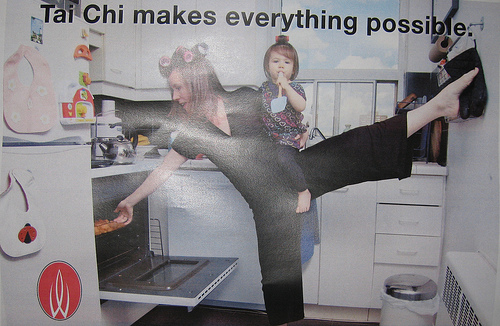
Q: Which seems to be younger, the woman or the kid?
A: The kid is younger than the woman.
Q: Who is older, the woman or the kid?
A: The woman is older than the kid.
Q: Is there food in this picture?
A: Yes, there is food.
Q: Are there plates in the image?
A: No, there are no plates.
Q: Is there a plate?
A: No, there are no plates.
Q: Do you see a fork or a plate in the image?
A: No, there are no plates or forks.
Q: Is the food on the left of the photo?
A: Yes, the food is on the left of the image.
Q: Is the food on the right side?
A: No, the food is on the left of the image.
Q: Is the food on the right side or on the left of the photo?
A: The food is on the left of the image.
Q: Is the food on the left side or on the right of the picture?
A: The food is on the left of the image.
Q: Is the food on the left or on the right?
A: The food is on the left of the image.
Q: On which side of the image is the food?
A: The food is on the left of the image.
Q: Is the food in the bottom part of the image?
A: Yes, the food is in the bottom of the image.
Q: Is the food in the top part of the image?
A: No, the food is in the bottom of the image.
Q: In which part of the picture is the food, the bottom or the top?
A: The food is in the bottom of the image.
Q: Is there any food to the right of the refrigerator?
A: Yes, there is food to the right of the refrigerator.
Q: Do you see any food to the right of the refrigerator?
A: Yes, there is food to the right of the refrigerator.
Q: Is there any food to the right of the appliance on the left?
A: Yes, there is food to the right of the refrigerator.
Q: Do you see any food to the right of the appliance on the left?
A: Yes, there is food to the right of the refrigerator.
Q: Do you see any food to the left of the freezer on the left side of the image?
A: No, the food is to the right of the freezer.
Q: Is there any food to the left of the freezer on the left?
A: No, the food is to the right of the freezer.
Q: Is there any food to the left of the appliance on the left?
A: No, the food is to the right of the freezer.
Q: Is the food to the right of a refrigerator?
A: Yes, the food is to the right of a refrigerator.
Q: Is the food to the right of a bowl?
A: No, the food is to the right of a refrigerator.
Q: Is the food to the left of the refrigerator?
A: No, the food is to the right of the refrigerator.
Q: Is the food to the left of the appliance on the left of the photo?
A: No, the food is to the right of the refrigerator.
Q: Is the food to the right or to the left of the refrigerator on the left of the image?
A: The food is to the right of the freezer.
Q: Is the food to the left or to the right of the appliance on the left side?
A: The food is to the right of the freezer.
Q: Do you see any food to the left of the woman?
A: Yes, there is food to the left of the woman.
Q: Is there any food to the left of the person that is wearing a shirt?
A: Yes, there is food to the left of the woman.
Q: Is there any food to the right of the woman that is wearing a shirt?
A: No, the food is to the left of the woman.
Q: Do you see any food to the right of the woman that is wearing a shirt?
A: No, the food is to the left of the woman.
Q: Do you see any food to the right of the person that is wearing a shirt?
A: No, the food is to the left of the woman.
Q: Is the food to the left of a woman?
A: Yes, the food is to the left of a woman.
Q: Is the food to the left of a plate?
A: No, the food is to the left of a woman.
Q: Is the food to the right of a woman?
A: No, the food is to the left of a woman.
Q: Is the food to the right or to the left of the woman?
A: The food is to the left of the woman.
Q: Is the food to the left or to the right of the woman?
A: The food is to the left of the woman.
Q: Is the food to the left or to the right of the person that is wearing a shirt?
A: The food is to the left of the woman.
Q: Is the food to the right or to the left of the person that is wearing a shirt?
A: The food is to the left of the woman.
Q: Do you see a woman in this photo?
A: Yes, there is a woman.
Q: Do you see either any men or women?
A: Yes, there is a woman.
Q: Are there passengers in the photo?
A: No, there are no passengers.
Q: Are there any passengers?
A: No, there are no passengers.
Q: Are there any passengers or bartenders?
A: No, there are no passengers or bartenders.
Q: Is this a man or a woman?
A: This is a woman.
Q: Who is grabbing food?
A: The woman is grabbing food.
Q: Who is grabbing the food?
A: The woman is grabbing food.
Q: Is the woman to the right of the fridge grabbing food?
A: Yes, the woman is grabbing food.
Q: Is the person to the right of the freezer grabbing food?
A: Yes, the woman is grabbing food.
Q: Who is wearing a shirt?
A: The woman is wearing a shirt.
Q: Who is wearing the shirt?
A: The woman is wearing a shirt.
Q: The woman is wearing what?
A: The woman is wearing a shirt.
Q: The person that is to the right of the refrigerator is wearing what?
A: The woman is wearing a shirt.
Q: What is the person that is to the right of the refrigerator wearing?
A: The woman is wearing a shirt.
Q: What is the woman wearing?
A: The woman is wearing a shirt.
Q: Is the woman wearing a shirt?
A: Yes, the woman is wearing a shirt.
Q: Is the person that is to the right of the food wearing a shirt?
A: Yes, the woman is wearing a shirt.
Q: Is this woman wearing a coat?
A: No, the woman is wearing a shirt.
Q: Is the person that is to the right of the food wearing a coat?
A: No, the woman is wearing a shirt.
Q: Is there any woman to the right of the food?
A: Yes, there is a woman to the right of the food.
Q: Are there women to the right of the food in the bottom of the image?
A: Yes, there is a woman to the right of the food.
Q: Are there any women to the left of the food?
A: No, the woman is to the right of the food.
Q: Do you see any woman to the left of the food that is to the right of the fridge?
A: No, the woman is to the right of the food.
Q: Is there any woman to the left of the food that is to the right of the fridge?
A: No, the woman is to the right of the food.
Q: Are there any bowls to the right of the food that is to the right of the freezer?
A: No, there is a woman to the right of the food.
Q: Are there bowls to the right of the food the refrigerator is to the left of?
A: No, there is a woman to the right of the food.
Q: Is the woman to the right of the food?
A: Yes, the woman is to the right of the food.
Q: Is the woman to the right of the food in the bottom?
A: Yes, the woman is to the right of the food.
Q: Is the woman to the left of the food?
A: No, the woman is to the right of the food.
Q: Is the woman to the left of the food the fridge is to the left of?
A: No, the woman is to the right of the food.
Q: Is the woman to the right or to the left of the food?
A: The woman is to the right of the food.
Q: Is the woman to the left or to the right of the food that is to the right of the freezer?
A: The woman is to the right of the food.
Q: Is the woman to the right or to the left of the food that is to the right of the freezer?
A: The woman is to the right of the food.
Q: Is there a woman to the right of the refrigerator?
A: Yes, there is a woman to the right of the refrigerator.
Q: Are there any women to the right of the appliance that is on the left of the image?
A: Yes, there is a woman to the right of the refrigerator.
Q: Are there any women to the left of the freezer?
A: No, the woman is to the right of the freezer.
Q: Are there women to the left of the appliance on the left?
A: No, the woman is to the right of the freezer.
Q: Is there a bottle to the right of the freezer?
A: No, there is a woman to the right of the freezer.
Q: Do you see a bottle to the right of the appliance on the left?
A: No, there is a woman to the right of the freezer.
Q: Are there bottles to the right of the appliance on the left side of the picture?
A: No, there is a woman to the right of the freezer.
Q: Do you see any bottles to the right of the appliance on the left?
A: No, there is a woman to the right of the freezer.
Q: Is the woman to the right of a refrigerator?
A: Yes, the woman is to the right of a refrigerator.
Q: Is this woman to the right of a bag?
A: No, the woman is to the right of a refrigerator.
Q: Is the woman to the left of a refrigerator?
A: No, the woman is to the right of a refrigerator.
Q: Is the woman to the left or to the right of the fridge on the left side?
A: The woman is to the right of the refrigerator.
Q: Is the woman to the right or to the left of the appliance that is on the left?
A: The woman is to the right of the refrigerator.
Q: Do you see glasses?
A: No, there are no glasses.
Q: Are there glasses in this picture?
A: No, there are no glasses.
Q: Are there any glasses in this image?
A: No, there are no glasses.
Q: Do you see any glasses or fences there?
A: No, there are no glasses or fences.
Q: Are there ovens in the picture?
A: Yes, there is an oven.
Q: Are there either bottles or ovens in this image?
A: Yes, there is an oven.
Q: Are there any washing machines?
A: No, there are no washing machines.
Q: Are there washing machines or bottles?
A: No, there are no washing machines or bottles.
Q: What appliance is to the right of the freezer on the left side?
A: The appliance is an oven.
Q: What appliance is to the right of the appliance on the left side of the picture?
A: The appliance is an oven.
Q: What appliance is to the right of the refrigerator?
A: The appliance is an oven.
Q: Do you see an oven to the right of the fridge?
A: Yes, there is an oven to the right of the fridge.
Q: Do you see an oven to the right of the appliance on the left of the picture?
A: Yes, there is an oven to the right of the fridge.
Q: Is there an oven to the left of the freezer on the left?
A: No, the oven is to the right of the freezer.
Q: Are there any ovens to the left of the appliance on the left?
A: No, the oven is to the right of the freezer.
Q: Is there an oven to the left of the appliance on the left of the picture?
A: No, the oven is to the right of the freezer.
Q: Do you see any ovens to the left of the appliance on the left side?
A: No, the oven is to the right of the freezer.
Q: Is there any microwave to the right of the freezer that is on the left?
A: No, there is an oven to the right of the fridge.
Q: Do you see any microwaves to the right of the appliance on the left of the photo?
A: No, there is an oven to the right of the fridge.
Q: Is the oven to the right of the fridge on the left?
A: Yes, the oven is to the right of the fridge.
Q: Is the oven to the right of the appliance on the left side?
A: Yes, the oven is to the right of the fridge.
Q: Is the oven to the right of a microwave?
A: No, the oven is to the right of the fridge.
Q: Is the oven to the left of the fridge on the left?
A: No, the oven is to the right of the refrigerator.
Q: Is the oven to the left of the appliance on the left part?
A: No, the oven is to the right of the refrigerator.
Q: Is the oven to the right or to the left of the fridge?
A: The oven is to the right of the fridge.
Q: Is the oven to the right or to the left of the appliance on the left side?
A: The oven is to the right of the fridge.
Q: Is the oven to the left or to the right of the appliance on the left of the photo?
A: The oven is to the right of the fridge.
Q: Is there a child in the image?
A: Yes, there is a child.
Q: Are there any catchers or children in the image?
A: Yes, there is a child.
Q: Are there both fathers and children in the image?
A: No, there is a child but no fathers.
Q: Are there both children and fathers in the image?
A: No, there is a child but no fathers.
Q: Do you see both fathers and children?
A: No, there is a child but no fathers.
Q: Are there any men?
A: No, there are no men.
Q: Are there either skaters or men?
A: No, there are no men or skaters.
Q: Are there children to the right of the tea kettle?
A: Yes, there is a child to the right of the tea kettle.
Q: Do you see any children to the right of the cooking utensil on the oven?
A: Yes, there is a child to the right of the tea kettle.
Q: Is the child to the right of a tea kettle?
A: Yes, the child is to the right of a tea kettle.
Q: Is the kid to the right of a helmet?
A: No, the kid is to the right of a tea kettle.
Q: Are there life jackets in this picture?
A: No, there are no life jackets.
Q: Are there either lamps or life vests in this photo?
A: No, there are no life vests or lamps.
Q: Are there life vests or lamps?
A: No, there are no life vests or lamps.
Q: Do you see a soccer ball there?
A: No, there are no soccer balls.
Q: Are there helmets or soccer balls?
A: No, there are no soccer balls or helmets.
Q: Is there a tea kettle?
A: Yes, there is a tea kettle.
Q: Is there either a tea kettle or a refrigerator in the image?
A: Yes, there is a tea kettle.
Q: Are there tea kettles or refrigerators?
A: Yes, there is a tea kettle.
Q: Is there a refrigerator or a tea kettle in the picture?
A: Yes, there is a tea kettle.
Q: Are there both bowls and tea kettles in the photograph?
A: No, there is a tea kettle but no bowls.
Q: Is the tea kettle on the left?
A: Yes, the tea kettle is on the left of the image.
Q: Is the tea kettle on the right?
A: No, the tea kettle is on the left of the image.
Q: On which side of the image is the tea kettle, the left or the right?
A: The tea kettle is on the left of the image.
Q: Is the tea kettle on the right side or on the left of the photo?
A: The tea kettle is on the left of the image.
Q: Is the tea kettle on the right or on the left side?
A: The tea kettle is on the left of the image.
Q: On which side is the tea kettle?
A: The tea kettle is on the left of the image.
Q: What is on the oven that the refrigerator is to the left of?
A: The tea kettle is on the oven.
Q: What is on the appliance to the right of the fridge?
A: The tea kettle is on the oven.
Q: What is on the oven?
A: The tea kettle is on the oven.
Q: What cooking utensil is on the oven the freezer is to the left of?
A: The cooking utensil is a tea kettle.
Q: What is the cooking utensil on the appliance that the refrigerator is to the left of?
A: The cooking utensil is a tea kettle.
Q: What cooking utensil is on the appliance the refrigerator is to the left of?
A: The cooking utensil is a tea kettle.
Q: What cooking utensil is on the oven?
A: The cooking utensil is a tea kettle.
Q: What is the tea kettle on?
A: The tea kettle is on the oven.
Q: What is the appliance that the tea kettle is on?
A: The appliance is an oven.